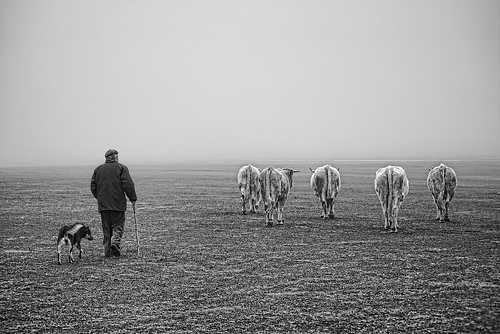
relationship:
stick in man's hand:
[127, 197, 148, 261] [125, 196, 142, 208]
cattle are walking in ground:
[427, 163, 457, 223] [0, 169, 495, 330]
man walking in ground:
[89, 149, 136, 256] [0, 169, 495, 330]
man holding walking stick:
[89, 149, 136, 256] [128, 194, 145, 254]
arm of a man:
[117, 163, 139, 205] [89, 149, 136, 256]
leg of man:
[100, 209, 110, 259] [83, 150, 138, 256]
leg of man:
[108, 210, 124, 256] [83, 150, 138, 256]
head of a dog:
[79, 220, 96, 242] [52, 217, 95, 267]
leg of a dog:
[54, 237, 64, 264] [51, 218, 94, 264]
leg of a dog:
[65, 239, 74, 265] [51, 218, 94, 264]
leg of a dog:
[76, 239, 83, 260] [51, 218, 94, 264]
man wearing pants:
[89, 149, 136, 256] [95, 206, 127, 246]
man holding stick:
[89, 149, 136, 256] [130, 201, 140, 254]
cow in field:
[234, 162, 264, 215] [5, 164, 494, 329]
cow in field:
[254, 164, 301, 228] [5, 164, 494, 329]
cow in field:
[308, 162, 343, 222] [5, 164, 494, 329]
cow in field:
[372, 161, 410, 233] [5, 164, 494, 329]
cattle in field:
[427, 163, 457, 223] [5, 164, 494, 329]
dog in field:
[18, 201, 123, 290] [5, 164, 494, 329]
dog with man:
[18, 201, 123, 290] [89, 149, 136, 256]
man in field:
[89, 149, 136, 256] [5, 164, 494, 329]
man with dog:
[89, 149, 136, 256] [18, 201, 123, 290]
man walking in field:
[89, 149, 136, 256] [5, 164, 494, 329]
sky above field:
[4, 3, 490, 159] [5, 164, 494, 329]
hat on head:
[105, 146, 118, 160] [102, 146, 122, 167]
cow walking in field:
[234, 162, 264, 215] [5, 164, 494, 329]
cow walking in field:
[254, 164, 301, 228] [5, 164, 494, 329]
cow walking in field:
[308, 162, 343, 222] [5, 164, 494, 329]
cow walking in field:
[372, 161, 410, 233] [5, 164, 494, 329]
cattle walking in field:
[427, 163, 457, 223] [5, 164, 494, 329]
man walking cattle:
[89, 149, 136, 256] [236, 157, 457, 234]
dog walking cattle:
[57, 223, 92, 265] [236, 157, 457, 234]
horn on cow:
[306, 165, 318, 172] [308, 162, 343, 222]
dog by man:
[47, 226, 96, 264] [90, 140, 137, 252]